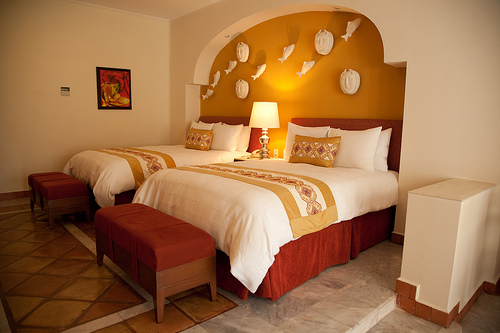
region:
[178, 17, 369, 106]
ocean-themed decorations on wall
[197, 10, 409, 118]
ochre wall with white decorations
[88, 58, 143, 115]
black-framed painting on a white wall.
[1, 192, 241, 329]
brown tiles in a diamond pattern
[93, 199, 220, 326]
wooden ottoman with red cushion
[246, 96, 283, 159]
metal lamp with white shade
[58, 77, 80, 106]
digital thermostat on white wall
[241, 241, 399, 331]
marble tile floor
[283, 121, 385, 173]
ochre and red pillow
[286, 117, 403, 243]
red headboard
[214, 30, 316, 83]
Fish on a yellow wall.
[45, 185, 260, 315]
Red ottoman at the end of a bed.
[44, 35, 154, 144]
Painting hanging against a white wall.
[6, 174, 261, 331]
Orange and brown floor tile.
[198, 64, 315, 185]
Lamp resting on night stand.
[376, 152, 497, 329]
Empty white pillar.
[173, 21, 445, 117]
Various ornaments above beds.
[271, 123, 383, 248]
Orange and white pillows.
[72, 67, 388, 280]
Matching bed set ups.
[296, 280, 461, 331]
White marble tile.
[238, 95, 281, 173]
the lamp shade is white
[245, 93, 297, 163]
the lamp is turned on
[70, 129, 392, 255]
the bedspreads are white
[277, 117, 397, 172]
the pillows are white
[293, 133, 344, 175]
the decorative pillow is gold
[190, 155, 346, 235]
the stripe on the bedspread is gold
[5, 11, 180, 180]
the walls are white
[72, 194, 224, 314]
the stool is brown and wooden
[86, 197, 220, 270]
the stool has brown cloth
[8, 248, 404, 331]
the floor is tile and marble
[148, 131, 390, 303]
Bed on the right of the room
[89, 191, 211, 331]
bench in front of the bed on the right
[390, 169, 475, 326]
small wall next to bed on the right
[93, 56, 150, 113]
picture hanging on the wall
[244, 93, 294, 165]
lap on table between the beds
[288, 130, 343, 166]
small pillow on bed on the right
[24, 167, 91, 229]
bench with red covering in front ot left bed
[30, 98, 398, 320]
two beds in the room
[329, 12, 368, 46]
highest fix on the wall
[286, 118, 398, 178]
white pillows on right hand bed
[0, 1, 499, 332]
an indoor scene of a bedroom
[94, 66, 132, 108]
a picture frame of artwork mounted on the wall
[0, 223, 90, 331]
Mexican tile floor at the foot of the bed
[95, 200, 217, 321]
a side bench with an orange cushion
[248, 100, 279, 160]
a bedside lamp on the table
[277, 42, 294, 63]
artwork mounted on the back wall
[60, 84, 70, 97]
the air conditioner thermostat control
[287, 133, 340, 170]
a throw down pillow on the bed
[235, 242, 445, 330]
grey colored tile floors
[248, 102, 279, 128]
a beige colored lamp shade